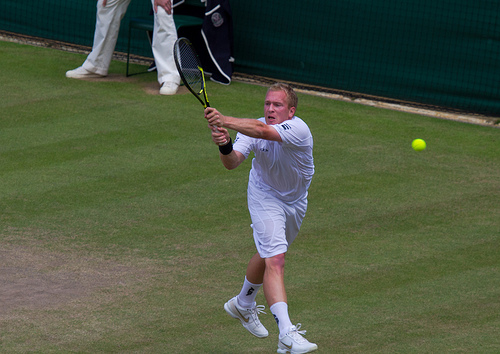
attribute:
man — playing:
[205, 76, 329, 353]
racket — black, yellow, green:
[170, 34, 227, 148]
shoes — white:
[271, 323, 319, 352]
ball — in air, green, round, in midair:
[408, 136, 427, 153]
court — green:
[2, 35, 499, 353]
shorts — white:
[241, 177, 310, 261]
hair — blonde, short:
[267, 78, 299, 114]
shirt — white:
[229, 112, 319, 206]